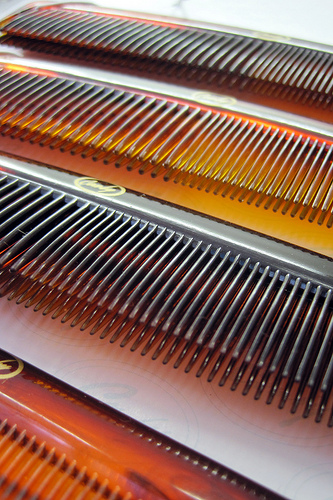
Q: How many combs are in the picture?
A: 4.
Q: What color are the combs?
A: Brown.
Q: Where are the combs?
A: On a white surface.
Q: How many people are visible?
A: None.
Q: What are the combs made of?
A: Plastic.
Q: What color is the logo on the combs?
A: Gold.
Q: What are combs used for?
A: Hair.